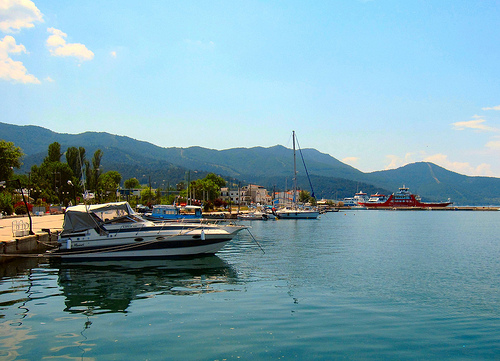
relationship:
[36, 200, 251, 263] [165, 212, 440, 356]
boat in water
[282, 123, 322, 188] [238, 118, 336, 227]
mast on boat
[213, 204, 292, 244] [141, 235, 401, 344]
cable in water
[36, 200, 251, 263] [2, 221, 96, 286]
boat on dock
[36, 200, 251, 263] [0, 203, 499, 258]
boat on harbor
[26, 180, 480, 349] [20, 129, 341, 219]
harbor by mountains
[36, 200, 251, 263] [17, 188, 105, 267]
boat by dock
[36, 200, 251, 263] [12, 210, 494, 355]
boat in water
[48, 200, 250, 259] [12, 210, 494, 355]
boat in water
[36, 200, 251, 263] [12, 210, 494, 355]
boat on water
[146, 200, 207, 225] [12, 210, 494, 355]
boat on water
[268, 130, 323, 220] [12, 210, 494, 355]
boat on water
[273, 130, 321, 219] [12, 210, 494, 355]
boat on water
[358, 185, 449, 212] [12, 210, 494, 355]
boat on water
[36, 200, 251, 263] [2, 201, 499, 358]
boat on water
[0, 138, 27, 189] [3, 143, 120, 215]
tree in field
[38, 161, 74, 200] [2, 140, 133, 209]
tree in field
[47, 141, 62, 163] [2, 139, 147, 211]
tree in field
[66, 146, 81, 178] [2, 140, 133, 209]
tree in field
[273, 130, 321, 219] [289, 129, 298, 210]
boat has mast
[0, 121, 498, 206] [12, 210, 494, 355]
mountains behind water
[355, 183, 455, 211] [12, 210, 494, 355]
boat on water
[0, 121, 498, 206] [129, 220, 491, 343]
mountains are behind water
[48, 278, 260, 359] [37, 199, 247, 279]
water reflects boat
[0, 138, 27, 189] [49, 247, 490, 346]
tree are beside water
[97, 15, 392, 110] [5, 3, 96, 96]
sky has clouds